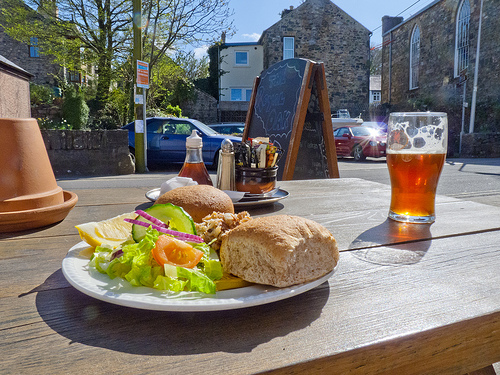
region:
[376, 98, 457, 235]
The glass is two thirds full.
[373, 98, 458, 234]
The glass is clear.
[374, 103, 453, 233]
The glass is in use.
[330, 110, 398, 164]
The car is red.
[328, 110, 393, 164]
The sun is glaring off of the car.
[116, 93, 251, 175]
The car is blue.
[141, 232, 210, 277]
The tomatoe wedge is yellow.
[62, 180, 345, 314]
Chopped lettuce in on the plate.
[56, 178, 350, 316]
A lemon wedge is on the plate.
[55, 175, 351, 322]
Two rolls are on the plate.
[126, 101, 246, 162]
the car is blue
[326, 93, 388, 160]
the car is red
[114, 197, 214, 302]
salad on the plate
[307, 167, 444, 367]
a wooden tan table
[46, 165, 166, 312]
a wooden tan table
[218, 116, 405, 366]
a wooden tan table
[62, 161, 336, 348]
food on the plate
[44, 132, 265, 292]
food on the plate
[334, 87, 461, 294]
beer in a glass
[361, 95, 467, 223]
glass on the table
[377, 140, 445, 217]
liquid in a glass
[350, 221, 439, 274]
shadow on the table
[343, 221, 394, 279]
line on the table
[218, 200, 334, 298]
bread on the plate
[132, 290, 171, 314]
white plate under food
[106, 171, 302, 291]
food on a plate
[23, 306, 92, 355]
shadow of the plate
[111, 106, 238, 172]
car in the background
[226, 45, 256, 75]
window on a building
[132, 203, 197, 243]
A green slice of cucumber.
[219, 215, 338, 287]
A light brown bread roll.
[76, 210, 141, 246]
A wedge of yellow lemon.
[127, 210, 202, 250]
Thin slices of purple onion.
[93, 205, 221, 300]
A salad.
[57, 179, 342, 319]
A plate of food.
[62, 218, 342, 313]
A round white plate.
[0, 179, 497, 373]
A brown wooden table.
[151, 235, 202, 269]
A red tomato slice.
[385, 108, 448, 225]
A tall glass cup.